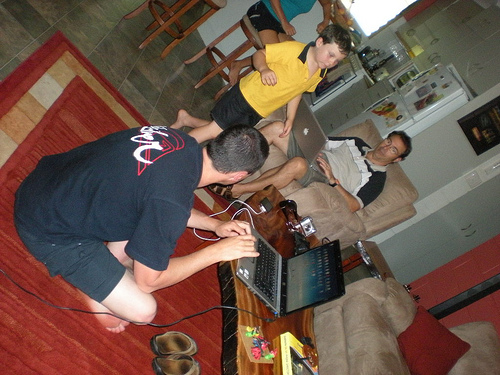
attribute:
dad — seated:
[323, 107, 411, 204]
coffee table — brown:
[220, 167, 327, 372]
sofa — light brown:
[313, 276, 497, 373]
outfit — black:
[30, 107, 213, 321]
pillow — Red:
[395, 304, 472, 374]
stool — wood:
[186, 15, 262, 97]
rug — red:
[39, 35, 115, 110]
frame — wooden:
[455, 95, 499, 155]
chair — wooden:
[128, 2, 225, 57]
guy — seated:
[7, 120, 273, 336]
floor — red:
[2, 0, 226, 372]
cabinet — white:
[419, 29, 491, 77]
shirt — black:
[11, 123, 204, 272]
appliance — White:
[322, 62, 495, 149]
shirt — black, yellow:
[231, 40, 330, 124]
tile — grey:
[115, 77, 154, 119]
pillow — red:
[397, 302, 469, 373]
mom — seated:
[243, 0, 336, 40]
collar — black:
[301, 42, 329, 79]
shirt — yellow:
[237, 42, 324, 116]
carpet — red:
[13, 60, 90, 124]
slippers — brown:
[144, 324, 202, 374]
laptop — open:
[230, 210, 347, 321]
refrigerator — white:
[319, 66, 469, 148]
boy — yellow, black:
[168, 21, 358, 146]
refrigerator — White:
[323, 60, 470, 140]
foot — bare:
[83, 295, 131, 336]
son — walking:
[233, 39, 366, 94]